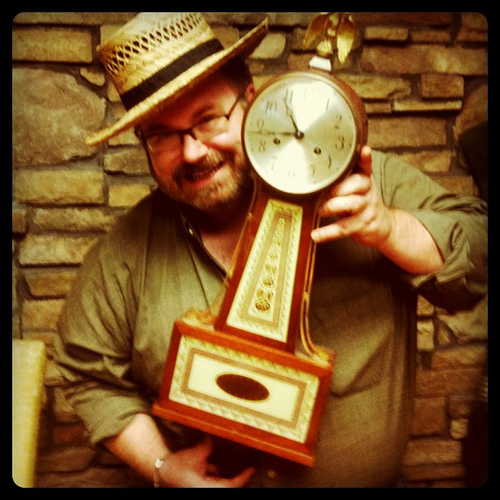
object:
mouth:
[176, 157, 229, 188]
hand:
[308, 143, 397, 250]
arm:
[380, 152, 489, 317]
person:
[53, 13, 487, 489]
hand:
[156, 438, 255, 490]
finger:
[190, 464, 263, 489]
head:
[130, 38, 261, 219]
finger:
[172, 435, 211, 472]